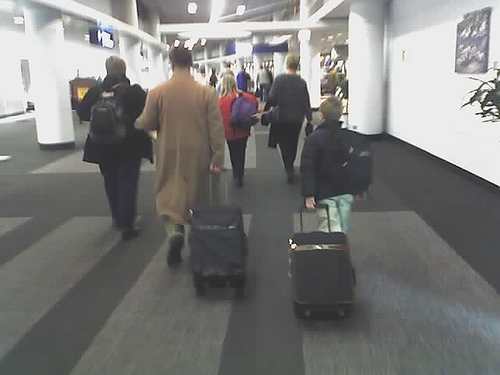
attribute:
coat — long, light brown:
[136, 68, 229, 224]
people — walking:
[84, 46, 367, 247]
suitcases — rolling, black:
[182, 168, 358, 319]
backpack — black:
[324, 129, 372, 191]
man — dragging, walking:
[140, 45, 231, 272]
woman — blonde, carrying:
[217, 75, 257, 185]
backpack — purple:
[223, 92, 259, 135]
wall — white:
[380, 1, 498, 190]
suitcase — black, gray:
[191, 202, 246, 297]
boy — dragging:
[303, 100, 359, 247]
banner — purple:
[251, 39, 291, 58]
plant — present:
[461, 67, 497, 122]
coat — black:
[82, 86, 154, 171]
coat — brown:
[143, 78, 230, 220]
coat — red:
[214, 91, 261, 143]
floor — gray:
[0, 104, 497, 374]